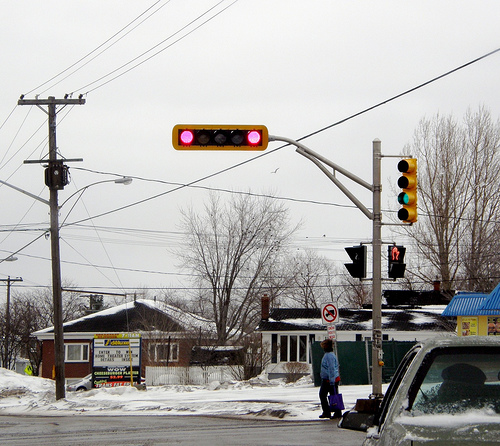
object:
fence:
[141, 362, 247, 387]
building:
[28, 294, 246, 394]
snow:
[0, 364, 391, 420]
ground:
[63, 398, 293, 443]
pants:
[317, 380, 338, 414]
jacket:
[318, 351, 340, 384]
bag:
[326, 391, 347, 412]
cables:
[21, 0, 239, 100]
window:
[63, 338, 101, 369]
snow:
[35, 297, 248, 331]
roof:
[34, 279, 249, 335]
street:
[0, 407, 380, 444]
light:
[397, 159, 406, 172]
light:
[395, 176, 410, 191]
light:
[397, 192, 411, 206]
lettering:
[95, 347, 139, 361]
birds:
[294, 229, 325, 256]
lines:
[57, 219, 491, 253]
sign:
[90, 332, 145, 391]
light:
[167, 122, 273, 152]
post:
[268, 134, 416, 395]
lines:
[57, 45, 498, 232]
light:
[395, 156, 417, 224]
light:
[394, 207, 410, 221]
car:
[362, 334, 499, 444]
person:
[318, 338, 345, 418]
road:
[6, 406, 245, 442]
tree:
[175, 187, 298, 346]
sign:
[319, 299, 339, 326]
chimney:
[258, 294, 270, 323]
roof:
[239, 281, 467, 334]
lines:
[276, 333, 280, 363]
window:
[267, 331, 318, 364]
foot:
[317, 412, 332, 419]